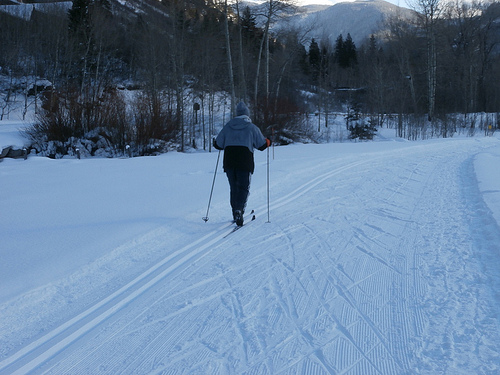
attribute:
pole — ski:
[260, 138, 286, 226]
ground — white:
[12, 225, 385, 367]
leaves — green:
[331, 30, 360, 70]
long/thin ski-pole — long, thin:
[263, 145, 272, 223]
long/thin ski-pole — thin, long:
[193, 142, 224, 230]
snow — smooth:
[0, 134, 403, 311]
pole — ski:
[200, 138, 229, 215]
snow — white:
[180, 221, 287, 315]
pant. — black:
[225, 169, 247, 213]